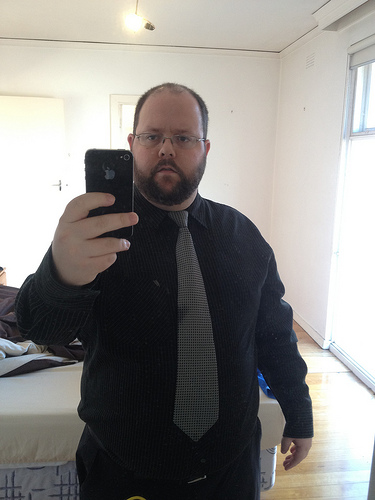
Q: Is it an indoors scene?
A: Yes, it is indoors.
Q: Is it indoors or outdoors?
A: It is indoors.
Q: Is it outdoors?
A: No, it is indoors.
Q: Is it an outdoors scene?
A: No, it is indoors.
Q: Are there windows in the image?
A: Yes, there is a window.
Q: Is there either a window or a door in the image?
A: Yes, there is a window.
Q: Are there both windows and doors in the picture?
A: Yes, there are both a window and a door.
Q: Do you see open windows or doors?
A: Yes, there is an open window.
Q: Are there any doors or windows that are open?
A: Yes, the window is open.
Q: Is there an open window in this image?
A: Yes, there is an open window.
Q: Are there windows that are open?
A: Yes, there is a window that is open.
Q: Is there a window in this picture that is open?
A: Yes, there is a window that is open.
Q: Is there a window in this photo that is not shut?
A: Yes, there is a open window.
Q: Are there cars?
A: No, there are no cars.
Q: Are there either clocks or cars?
A: No, there are no cars or clocks.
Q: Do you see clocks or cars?
A: No, there are no cars or clocks.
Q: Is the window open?
A: Yes, the window is open.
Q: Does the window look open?
A: Yes, the window is open.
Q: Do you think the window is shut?
A: No, the window is open.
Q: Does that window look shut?
A: No, the window is open.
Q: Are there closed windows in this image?
A: No, there is a window but it is open.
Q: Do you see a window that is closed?
A: No, there is a window but it is open.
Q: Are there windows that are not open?
A: No, there is a window but it is open.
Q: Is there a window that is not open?
A: No, there is a window but it is open.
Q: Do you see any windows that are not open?
A: No, there is a window but it is open.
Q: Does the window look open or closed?
A: The window is open.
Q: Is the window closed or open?
A: The window is open.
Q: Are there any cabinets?
A: No, there are no cabinets.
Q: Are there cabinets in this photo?
A: No, there are no cabinets.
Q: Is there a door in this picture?
A: Yes, there is a door.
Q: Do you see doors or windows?
A: Yes, there is a door.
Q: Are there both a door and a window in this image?
A: Yes, there are both a door and a window.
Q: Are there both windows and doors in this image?
A: Yes, there are both a door and a window.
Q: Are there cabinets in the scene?
A: No, there are no cabinets.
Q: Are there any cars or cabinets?
A: No, there are no cabinets or cars.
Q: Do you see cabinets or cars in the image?
A: No, there are no cabinets or cars.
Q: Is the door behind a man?
A: Yes, the door is behind a man.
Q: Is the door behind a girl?
A: No, the door is behind a man.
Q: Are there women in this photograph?
A: No, there are no women.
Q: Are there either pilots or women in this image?
A: No, there are no women or pilots.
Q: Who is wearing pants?
A: The man is wearing pants.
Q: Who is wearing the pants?
A: The man is wearing pants.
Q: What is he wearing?
A: The man is wearing pants.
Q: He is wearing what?
A: The man is wearing pants.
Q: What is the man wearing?
A: The man is wearing pants.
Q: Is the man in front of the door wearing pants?
A: Yes, the man is wearing pants.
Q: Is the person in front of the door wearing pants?
A: Yes, the man is wearing pants.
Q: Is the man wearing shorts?
A: No, the man is wearing pants.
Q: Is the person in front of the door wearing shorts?
A: No, the man is wearing pants.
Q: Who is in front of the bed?
A: The man is in front of the bed.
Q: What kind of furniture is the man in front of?
A: The man is in front of the bed.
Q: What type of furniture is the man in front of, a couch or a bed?
A: The man is in front of a bed.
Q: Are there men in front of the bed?
A: Yes, there is a man in front of the bed.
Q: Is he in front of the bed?
A: Yes, the man is in front of the bed.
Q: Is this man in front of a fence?
A: No, the man is in front of the bed.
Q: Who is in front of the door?
A: The man is in front of the door.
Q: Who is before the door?
A: The man is in front of the door.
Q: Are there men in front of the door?
A: Yes, there is a man in front of the door.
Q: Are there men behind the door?
A: No, the man is in front of the door.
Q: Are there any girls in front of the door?
A: No, there is a man in front of the door.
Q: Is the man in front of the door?
A: Yes, the man is in front of the door.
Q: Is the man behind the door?
A: No, the man is in front of the door.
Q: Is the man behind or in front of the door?
A: The man is in front of the door.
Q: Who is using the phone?
A: The man is using the phone.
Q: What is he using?
A: The man is using a telephone.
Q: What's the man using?
A: The man is using a telephone.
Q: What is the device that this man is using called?
A: The device is a phone.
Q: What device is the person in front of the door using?
A: The man is using a phone.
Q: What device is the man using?
A: The man is using a phone.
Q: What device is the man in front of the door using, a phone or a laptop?
A: The man is using a phone.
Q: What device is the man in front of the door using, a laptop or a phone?
A: The man is using a phone.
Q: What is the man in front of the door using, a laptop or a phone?
A: The man is using a phone.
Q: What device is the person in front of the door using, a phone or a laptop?
A: The man is using a phone.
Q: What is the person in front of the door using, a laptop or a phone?
A: The man is using a phone.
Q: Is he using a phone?
A: Yes, the man is using a phone.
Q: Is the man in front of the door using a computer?
A: No, the man is using a phone.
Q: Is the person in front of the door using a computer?
A: No, the man is using a phone.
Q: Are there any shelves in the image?
A: No, there are no shelves.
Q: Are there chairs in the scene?
A: No, there are no chairs.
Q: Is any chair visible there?
A: No, there are no chairs.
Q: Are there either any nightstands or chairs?
A: No, there are no chairs or nightstands.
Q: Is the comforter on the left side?
A: Yes, the comforter is on the left of the image.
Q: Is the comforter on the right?
A: No, the comforter is on the left of the image.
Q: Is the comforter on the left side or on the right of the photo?
A: The comforter is on the left of the image.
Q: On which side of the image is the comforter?
A: The comforter is on the left of the image.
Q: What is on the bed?
A: The comforter is on the bed.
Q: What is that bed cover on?
A: The bed cover is on the bed.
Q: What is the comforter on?
A: The bed cover is on the bed.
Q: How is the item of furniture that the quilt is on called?
A: The piece of furniture is a bed.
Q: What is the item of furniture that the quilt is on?
A: The piece of furniture is a bed.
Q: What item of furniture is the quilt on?
A: The quilt is on the bed.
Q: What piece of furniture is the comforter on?
A: The quilt is on the bed.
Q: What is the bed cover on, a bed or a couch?
A: The bed cover is on a bed.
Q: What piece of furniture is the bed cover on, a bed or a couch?
A: The bed cover is on a bed.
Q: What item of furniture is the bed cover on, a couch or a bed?
A: The bed cover is on a bed.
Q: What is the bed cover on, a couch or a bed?
A: The bed cover is on a bed.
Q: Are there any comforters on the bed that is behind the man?
A: Yes, there is a comforter on the bed.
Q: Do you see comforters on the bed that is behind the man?
A: Yes, there is a comforter on the bed.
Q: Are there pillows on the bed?
A: No, there is a comforter on the bed.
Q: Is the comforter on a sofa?
A: No, the comforter is on the bed.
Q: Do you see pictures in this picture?
A: No, there are no pictures.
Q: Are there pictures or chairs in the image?
A: No, there are no pictures or chairs.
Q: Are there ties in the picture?
A: Yes, there is a tie.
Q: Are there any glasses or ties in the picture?
A: Yes, there is a tie.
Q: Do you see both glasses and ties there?
A: Yes, there are both a tie and glasses.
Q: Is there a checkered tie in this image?
A: Yes, there is a checkered tie.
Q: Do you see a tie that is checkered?
A: Yes, there is a tie that is checkered.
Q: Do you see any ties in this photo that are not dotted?
A: Yes, there is a checkered tie.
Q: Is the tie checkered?
A: Yes, the tie is checkered.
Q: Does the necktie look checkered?
A: Yes, the necktie is checkered.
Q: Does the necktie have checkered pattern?
A: Yes, the necktie is checkered.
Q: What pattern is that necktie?
A: The necktie is checkered.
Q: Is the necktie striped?
A: No, the necktie is checkered.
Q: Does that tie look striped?
A: No, the tie is checkered.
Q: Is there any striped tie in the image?
A: No, there is a tie but it is checkered.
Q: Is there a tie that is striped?
A: No, there is a tie but it is checkered.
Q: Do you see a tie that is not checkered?
A: No, there is a tie but it is checkered.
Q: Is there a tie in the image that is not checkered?
A: No, there is a tie but it is checkered.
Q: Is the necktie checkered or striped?
A: The necktie is checkered.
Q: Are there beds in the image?
A: Yes, there is a bed.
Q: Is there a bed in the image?
A: Yes, there is a bed.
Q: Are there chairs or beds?
A: Yes, there is a bed.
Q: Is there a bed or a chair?
A: Yes, there is a bed.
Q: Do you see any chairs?
A: No, there are no chairs.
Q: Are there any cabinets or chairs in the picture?
A: No, there are no chairs or cabinets.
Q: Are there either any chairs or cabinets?
A: No, there are no chairs or cabinets.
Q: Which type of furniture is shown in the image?
A: The furniture is a bed.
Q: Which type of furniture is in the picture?
A: The furniture is a bed.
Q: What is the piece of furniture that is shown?
A: The piece of furniture is a bed.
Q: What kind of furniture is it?
A: The piece of furniture is a bed.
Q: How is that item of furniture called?
A: This is a bed.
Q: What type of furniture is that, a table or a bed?
A: This is a bed.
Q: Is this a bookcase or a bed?
A: This is a bed.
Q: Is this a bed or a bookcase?
A: This is a bed.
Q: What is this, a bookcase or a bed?
A: This is a bed.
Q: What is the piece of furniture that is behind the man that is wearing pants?
A: The piece of furniture is a bed.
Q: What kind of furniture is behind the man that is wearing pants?
A: The piece of furniture is a bed.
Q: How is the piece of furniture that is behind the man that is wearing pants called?
A: The piece of furniture is a bed.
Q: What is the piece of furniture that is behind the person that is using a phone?
A: The piece of furniture is a bed.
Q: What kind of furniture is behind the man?
A: The piece of furniture is a bed.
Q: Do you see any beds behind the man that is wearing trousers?
A: Yes, there is a bed behind the man.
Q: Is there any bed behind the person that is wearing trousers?
A: Yes, there is a bed behind the man.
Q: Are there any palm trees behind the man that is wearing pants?
A: No, there is a bed behind the man.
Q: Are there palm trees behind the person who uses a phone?
A: No, there is a bed behind the man.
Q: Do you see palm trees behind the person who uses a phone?
A: No, there is a bed behind the man.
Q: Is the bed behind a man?
A: Yes, the bed is behind a man.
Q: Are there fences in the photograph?
A: No, there are no fences.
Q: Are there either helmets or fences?
A: No, there are no fences or helmets.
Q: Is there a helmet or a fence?
A: No, there are no fences or helmets.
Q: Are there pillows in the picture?
A: No, there are no pillows.